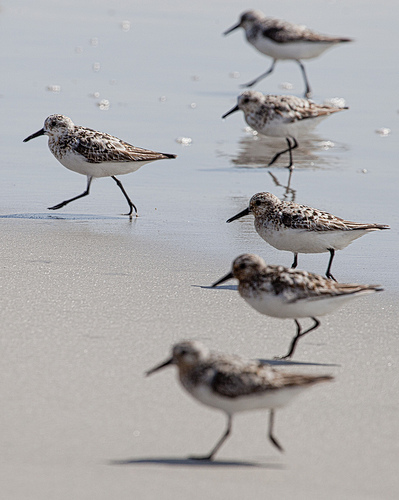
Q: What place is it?
A: It is a sea.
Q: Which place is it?
A: It is a sea.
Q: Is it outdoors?
A: Yes, it is outdoors.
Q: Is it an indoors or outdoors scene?
A: It is outdoors.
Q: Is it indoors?
A: No, it is outdoors.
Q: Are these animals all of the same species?
A: Yes, all the animals are birds.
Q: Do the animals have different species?
A: No, all the animals are birds.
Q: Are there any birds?
A: Yes, there is a bird.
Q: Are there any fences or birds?
A: Yes, there is a bird.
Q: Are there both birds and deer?
A: No, there is a bird but no deer.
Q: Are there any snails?
A: No, there are no snails.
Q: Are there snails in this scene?
A: No, there are no snails.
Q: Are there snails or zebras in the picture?
A: No, there are no snails or zebras.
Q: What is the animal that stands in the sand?
A: The animal is a bird.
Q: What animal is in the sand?
A: The animal is a bird.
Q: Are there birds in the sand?
A: Yes, there is a bird in the sand.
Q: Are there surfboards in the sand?
A: No, there is a bird in the sand.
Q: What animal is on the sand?
A: The animal is a bird.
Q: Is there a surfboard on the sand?
A: No, there is a bird on the sand.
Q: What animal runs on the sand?
A: The bird runs on the sand.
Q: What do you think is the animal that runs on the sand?
A: The animal is a bird.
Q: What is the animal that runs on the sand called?
A: The animal is a bird.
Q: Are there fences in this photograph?
A: No, there are no fences.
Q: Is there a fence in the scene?
A: No, there are no fences.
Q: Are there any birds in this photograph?
A: Yes, there is a bird.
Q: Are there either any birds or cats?
A: Yes, there is a bird.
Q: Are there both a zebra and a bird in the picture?
A: No, there is a bird but no zebras.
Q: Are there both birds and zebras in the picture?
A: No, there is a bird but no zebras.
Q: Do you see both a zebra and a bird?
A: No, there is a bird but no zebras.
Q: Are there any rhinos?
A: No, there are no rhinos.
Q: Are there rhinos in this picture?
A: No, there are no rhinos.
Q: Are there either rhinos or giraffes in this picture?
A: No, there are no rhinos or giraffes.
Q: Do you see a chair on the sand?
A: No, there is a bird on the sand.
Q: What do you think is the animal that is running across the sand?
A: The animal is a bird.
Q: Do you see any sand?
A: Yes, there is sand.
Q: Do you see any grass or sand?
A: Yes, there is sand.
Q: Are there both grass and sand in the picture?
A: No, there is sand but no grass.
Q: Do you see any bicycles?
A: No, there are no bicycles.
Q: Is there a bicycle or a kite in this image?
A: No, there are no bicycles or kites.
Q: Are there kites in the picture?
A: No, there are no kites.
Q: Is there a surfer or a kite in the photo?
A: No, there are no kites or surfers.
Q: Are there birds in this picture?
A: Yes, there is a bird.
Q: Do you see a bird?
A: Yes, there is a bird.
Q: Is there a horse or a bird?
A: Yes, there is a bird.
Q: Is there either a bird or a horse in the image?
A: Yes, there is a bird.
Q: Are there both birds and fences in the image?
A: No, there is a bird but no fences.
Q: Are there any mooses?
A: No, there are no mooses.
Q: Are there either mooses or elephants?
A: No, there are no mooses or elephants.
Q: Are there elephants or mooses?
A: No, there are no mooses or elephants.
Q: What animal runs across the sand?
A: The bird runs across the sand.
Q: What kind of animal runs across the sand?
A: The animal is a bird.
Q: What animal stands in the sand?
A: The bird stands in the sand.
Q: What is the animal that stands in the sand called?
A: The animal is a bird.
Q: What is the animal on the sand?
A: The animal is a bird.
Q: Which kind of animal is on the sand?
A: The animal is a bird.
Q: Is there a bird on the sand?
A: Yes, there is a bird on the sand.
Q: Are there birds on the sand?
A: Yes, there is a bird on the sand.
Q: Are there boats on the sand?
A: No, there is a bird on the sand.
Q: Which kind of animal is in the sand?
A: The animal is a bird.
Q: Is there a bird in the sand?
A: Yes, there is a bird in the sand.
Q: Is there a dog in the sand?
A: No, there is a bird in the sand.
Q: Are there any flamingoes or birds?
A: Yes, there is a bird.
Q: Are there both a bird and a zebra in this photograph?
A: No, there is a bird but no zebras.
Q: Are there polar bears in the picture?
A: No, there are no polar bears.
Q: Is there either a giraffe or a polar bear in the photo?
A: No, there are no polar bears or giraffes.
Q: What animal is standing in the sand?
A: The animal is a bird.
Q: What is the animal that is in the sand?
A: The animal is a bird.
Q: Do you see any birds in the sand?
A: Yes, there is a bird in the sand.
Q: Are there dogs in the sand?
A: No, there is a bird in the sand.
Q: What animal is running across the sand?
A: The bird is running across the sand.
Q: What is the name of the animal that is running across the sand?
A: The animal is a bird.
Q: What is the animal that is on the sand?
A: The animal is a bird.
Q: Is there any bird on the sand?
A: Yes, there is a bird on the sand.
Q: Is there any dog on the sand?
A: No, there is a bird on the sand.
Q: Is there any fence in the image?
A: No, there are no fences.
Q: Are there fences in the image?
A: No, there are no fences.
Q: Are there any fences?
A: No, there are no fences.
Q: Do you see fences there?
A: No, there are no fences.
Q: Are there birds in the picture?
A: Yes, there is a bird.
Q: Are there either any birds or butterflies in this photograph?
A: Yes, there is a bird.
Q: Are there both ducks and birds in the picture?
A: No, there is a bird but no ducks.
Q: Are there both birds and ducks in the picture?
A: No, there is a bird but no ducks.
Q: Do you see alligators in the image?
A: No, there are no alligators.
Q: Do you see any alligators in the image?
A: No, there are no alligators.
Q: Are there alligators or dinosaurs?
A: No, there are no alligators or dinosaurs.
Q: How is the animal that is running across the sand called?
A: The animal is a bird.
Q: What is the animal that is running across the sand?
A: The animal is a bird.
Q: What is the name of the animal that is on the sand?
A: The animal is a bird.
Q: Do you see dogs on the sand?
A: No, there is a bird on the sand.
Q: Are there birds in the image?
A: Yes, there is a bird.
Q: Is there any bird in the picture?
A: Yes, there is a bird.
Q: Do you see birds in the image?
A: Yes, there is a bird.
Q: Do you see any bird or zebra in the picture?
A: Yes, there is a bird.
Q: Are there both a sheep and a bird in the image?
A: No, there is a bird but no sheep.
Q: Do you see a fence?
A: No, there are no fences.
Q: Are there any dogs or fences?
A: No, there are no fences or dogs.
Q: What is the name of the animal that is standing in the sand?
A: The animal is a bird.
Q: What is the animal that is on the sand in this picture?
A: The animal is a bird.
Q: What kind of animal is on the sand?
A: The animal is a bird.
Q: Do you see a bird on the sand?
A: Yes, there is a bird on the sand.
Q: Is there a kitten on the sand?
A: No, there is a bird on the sand.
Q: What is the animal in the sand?
A: The animal is a bird.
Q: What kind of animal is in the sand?
A: The animal is a bird.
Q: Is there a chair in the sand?
A: No, there is a bird in the sand.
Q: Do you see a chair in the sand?
A: No, there is a bird in the sand.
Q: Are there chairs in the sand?
A: No, there is a bird in the sand.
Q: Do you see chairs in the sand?
A: No, there is a bird in the sand.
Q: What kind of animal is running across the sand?
A: The animal is a bird.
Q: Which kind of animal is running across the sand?
A: The animal is a bird.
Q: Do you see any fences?
A: No, there are no fences.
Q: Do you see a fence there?
A: No, there are no fences.